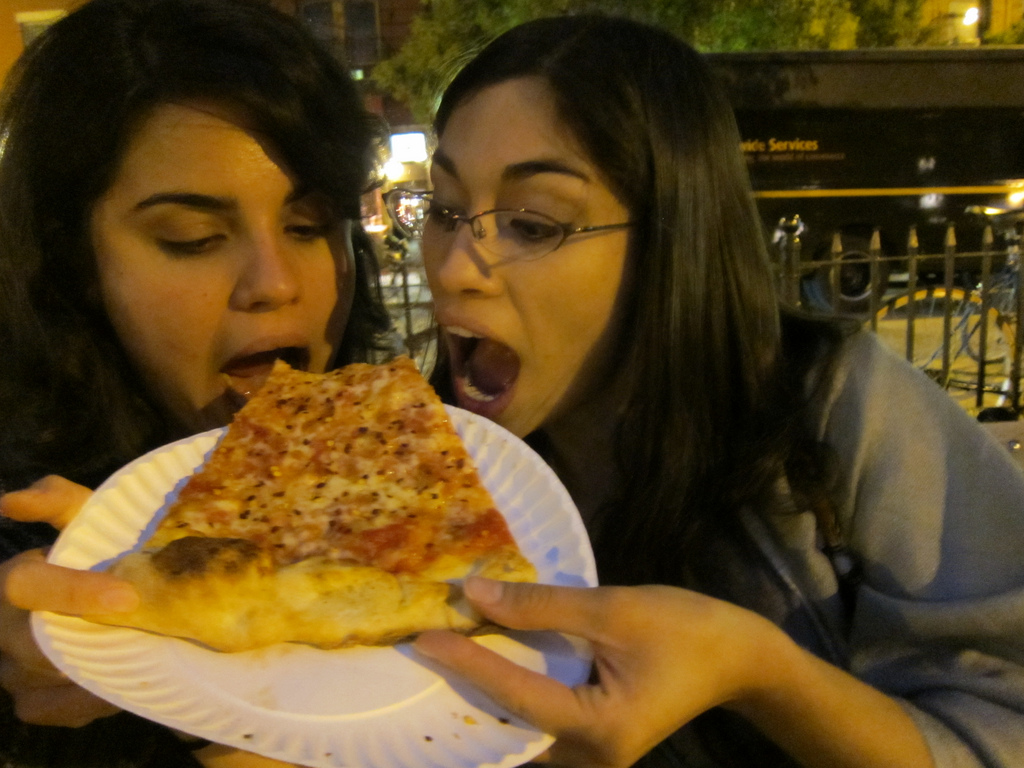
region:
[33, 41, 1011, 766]
two girls eating a pizza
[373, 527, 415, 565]
sauce on the pizza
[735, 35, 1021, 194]
black van in back of the fence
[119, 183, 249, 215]
black eyebrow of the girl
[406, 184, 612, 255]
glasses on the face of the girl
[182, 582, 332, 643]
crust on the pizza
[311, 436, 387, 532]
cheese on top of the pizza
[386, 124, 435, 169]
lighted sign across the street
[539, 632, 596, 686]
shadow of the hand on the plate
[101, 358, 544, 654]
the large slice of pizza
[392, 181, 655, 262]
the pair of glasses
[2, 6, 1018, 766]
the two women holding the plate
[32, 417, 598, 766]
the plate is white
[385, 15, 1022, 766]
the woman has dark hair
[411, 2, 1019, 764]
the woman has her mouth opened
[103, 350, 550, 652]
the toppings on the pizza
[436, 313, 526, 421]
the mouth is opened very wide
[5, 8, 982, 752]
Ladies sharing pizza slice.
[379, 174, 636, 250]
Pair of wire frame eyeglasses.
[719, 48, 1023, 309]
Black vehicle in background.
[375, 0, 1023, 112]
Green trees in background.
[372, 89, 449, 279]
Bright lights are shining.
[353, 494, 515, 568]
Pepperoni on pizza.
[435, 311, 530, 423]
Open mouth with white teeth.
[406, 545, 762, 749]
Thumb and finger on plate.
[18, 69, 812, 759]
A couple of ladys eating.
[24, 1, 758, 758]
A couple of ladys eating a pizza.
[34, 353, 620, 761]
A piece of pizza on a white plate.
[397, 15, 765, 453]
A brown haired lady with glasses.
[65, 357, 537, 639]
A piece of cheese pizza.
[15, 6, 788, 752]
A couple of lady's sharing a pizza.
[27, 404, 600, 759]
A white paper plate .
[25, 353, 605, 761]
A white paper plate under the pizza.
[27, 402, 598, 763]
A white paper plate.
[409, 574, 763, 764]
A left hand holding a pizza crust.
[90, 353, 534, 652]
A slice of pizza on a plate.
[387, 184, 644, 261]
Thin framed glasses on a woman's face.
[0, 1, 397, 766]
A darker haired woman with her mouth open.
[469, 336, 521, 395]
A tongue in a mouth of a girl with glasses.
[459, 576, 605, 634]
A woman's left thumb touching a pizza crust.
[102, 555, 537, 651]
A crust on a pizza.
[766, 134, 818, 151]
The word Services on a truck.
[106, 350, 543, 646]
a piece of pizza with a few bites missing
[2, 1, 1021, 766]
two girls sharing the same piece of pizza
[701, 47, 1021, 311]
a black service trailer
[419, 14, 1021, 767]
a woman with black hair and glasses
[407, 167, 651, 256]
The lady is wearing glasses.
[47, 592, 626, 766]
The plate is white.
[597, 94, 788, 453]
The lady has long black hair.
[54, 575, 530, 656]
The crust of the pizza.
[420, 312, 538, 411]
The lady mouth is open.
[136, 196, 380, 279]
The woman eyes are barely closed.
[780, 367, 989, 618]
The jacket is gray.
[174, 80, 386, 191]
The woman has a bang in front of her head.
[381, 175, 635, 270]
thin wire framed glasses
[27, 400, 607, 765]
pizza on white paper plate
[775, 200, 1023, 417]
fencing made of metal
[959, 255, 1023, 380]
wheel opf a bicycle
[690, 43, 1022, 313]
a UPS delivery truck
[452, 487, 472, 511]
black topping on pizza